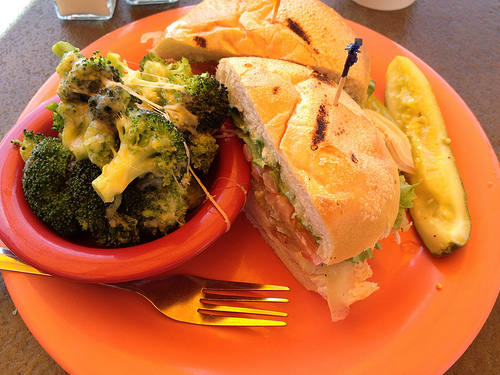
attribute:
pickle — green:
[385, 57, 486, 253]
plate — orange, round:
[452, 91, 499, 159]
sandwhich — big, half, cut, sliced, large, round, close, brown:
[241, 56, 398, 263]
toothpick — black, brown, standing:
[330, 33, 374, 110]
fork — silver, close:
[196, 272, 304, 347]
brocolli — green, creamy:
[66, 58, 196, 205]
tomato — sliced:
[197, 38, 404, 290]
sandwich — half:
[214, 35, 404, 308]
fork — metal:
[4, 195, 321, 353]